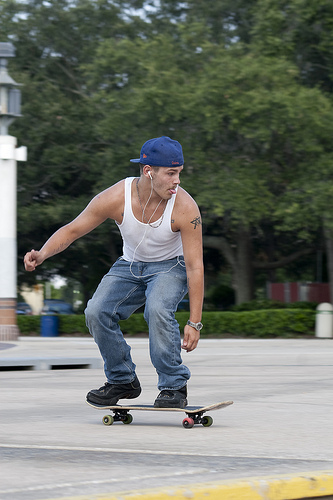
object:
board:
[82, 398, 233, 429]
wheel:
[182, 417, 193, 429]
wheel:
[102, 415, 111, 426]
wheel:
[202, 415, 213, 427]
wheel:
[122, 412, 133, 423]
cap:
[128, 135, 184, 168]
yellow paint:
[87, 477, 332, 500]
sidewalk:
[0, 337, 333, 500]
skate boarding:
[22, 134, 232, 427]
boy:
[23, 137, 204, 408]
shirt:
[114, 176, 183, 263]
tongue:
[169, 188, 176, 193]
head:
[138, 136, 184, 199]